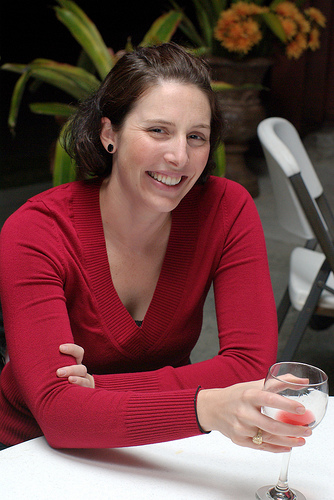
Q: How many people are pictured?
A: 1.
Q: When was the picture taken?
A: Daytime.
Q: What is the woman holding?
A: Glass.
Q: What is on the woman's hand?
A: Ring.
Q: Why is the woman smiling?
A: Happy.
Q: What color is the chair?
A: White.